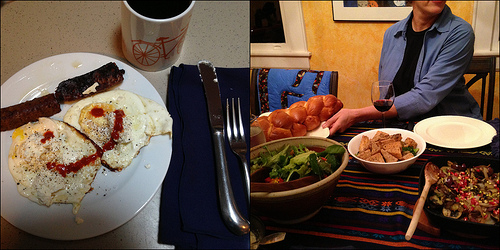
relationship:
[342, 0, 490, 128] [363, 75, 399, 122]
woman near cup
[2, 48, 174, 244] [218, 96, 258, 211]
plate beside fork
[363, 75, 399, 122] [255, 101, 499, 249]
cup on table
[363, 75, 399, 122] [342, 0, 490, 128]
cup near woman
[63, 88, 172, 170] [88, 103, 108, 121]
egg with red sauce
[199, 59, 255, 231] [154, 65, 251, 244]
butter knife on a napkin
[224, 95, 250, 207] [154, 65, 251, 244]
fork on a napkin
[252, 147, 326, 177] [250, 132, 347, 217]
green salad in a bowl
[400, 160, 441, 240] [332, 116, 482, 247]
utensil on table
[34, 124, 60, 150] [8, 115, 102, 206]
eye on egg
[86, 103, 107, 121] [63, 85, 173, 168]
eye on egg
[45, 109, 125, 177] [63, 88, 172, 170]
smile on egg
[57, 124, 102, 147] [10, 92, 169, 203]
pepper on top of eggs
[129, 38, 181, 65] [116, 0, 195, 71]
red bike on a cup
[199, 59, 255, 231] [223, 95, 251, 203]
butter knife next to fork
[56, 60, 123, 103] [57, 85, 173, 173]
sausage next to egg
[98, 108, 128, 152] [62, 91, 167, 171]
red sauce drizzled on egg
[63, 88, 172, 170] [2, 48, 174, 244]
egg on a plate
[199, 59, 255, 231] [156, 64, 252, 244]
butter knife on a blue napkin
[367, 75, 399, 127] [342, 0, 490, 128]
cup in front of woman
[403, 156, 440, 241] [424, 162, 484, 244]
wooden spoon resting in a black tray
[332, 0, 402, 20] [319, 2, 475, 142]
art work behind a woman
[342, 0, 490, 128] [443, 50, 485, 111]
woman sitting in a wooden chair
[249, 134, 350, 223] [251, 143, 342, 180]
bowl filled with green salad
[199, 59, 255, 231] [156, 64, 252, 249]
butter knife sitting on blue napkin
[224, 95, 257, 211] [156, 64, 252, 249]
fork sitting on blue napkin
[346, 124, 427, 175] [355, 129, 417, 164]
bowl filled with bread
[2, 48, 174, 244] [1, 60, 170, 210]
plate holding food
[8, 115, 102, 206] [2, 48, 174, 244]
egg on plate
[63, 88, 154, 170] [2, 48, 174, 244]
egg on plate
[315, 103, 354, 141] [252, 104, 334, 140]
hand holding platter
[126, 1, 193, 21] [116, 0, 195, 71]
coffee in cup